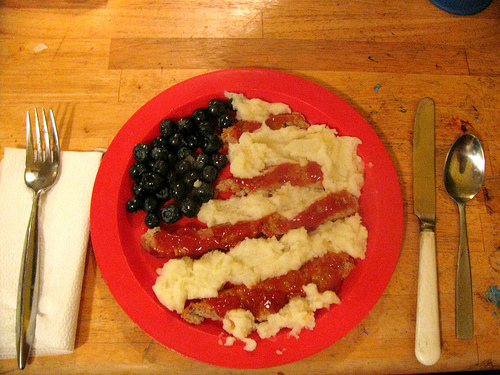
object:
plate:
[87, 68, 403, 369]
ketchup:
[221, 112, 309, 143]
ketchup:
[228, 162, 324, 188]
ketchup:
[149, 192, 352, 258]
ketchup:
[208, 253, 342, 317]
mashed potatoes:
[229, 121, 365, 197]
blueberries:
[144, 213, 159, 227]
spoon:
[443, 132, 485, 339]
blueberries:
[205, 98, 227, 116]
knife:
[411, 97, 443, 367]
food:
[224, 91, 292, 123]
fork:
[15, 107, 61, 365]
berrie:
[160, 119, 177, 137]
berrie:
[212, 153, 229, 167]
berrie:
[161, 205, 180, 224]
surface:
[0, 0, 499, 375]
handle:
[414, 232, 442, 366]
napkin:
[0, 148, 103, 360]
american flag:
[127, 92, 368, 351]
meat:
[141, 191, 360, 257]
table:
[0, 0, 499, 375]